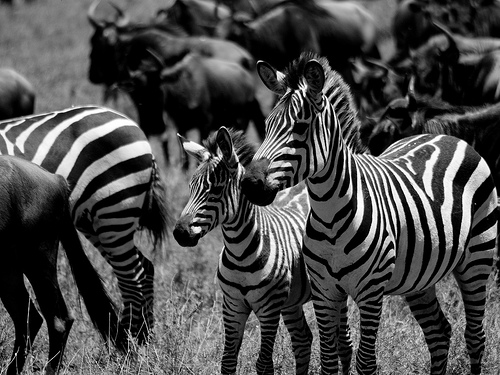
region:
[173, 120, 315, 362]
zebra colt next to mother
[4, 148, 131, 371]
rear legs and tail of horse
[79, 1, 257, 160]
water buffalo or musk ox in background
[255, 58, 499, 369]
zebra next to colt looking to the left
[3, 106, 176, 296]
rear legs and tail of zebra on far left of picture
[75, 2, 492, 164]
herd of water buffalo or musk oxen in background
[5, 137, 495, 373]
grass in field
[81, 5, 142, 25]
horns of large water buffalo in background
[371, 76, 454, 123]
water buffalo looking to the right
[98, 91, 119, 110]
water buffalo in background's beard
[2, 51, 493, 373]
zebras standing on the grass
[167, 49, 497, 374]
baby zebra standing next to an adult zebra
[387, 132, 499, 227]
black and white stripes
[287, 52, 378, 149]
tall hair along the neck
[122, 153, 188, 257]
hair on the tail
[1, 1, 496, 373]
a bunch of animals on the grass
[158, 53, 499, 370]
two black and white zebras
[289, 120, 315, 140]
black eye on the side of the head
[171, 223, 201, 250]
tip of the snout is black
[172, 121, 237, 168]
two long ears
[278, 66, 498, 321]
white and black zebra on grass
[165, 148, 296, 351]
white and black zebra on grass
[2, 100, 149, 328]
white and black zebra on grass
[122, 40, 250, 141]
brown wildebeest in grass field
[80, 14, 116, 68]
brown wildebeest in grass field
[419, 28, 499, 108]
brown wildebeest in grass field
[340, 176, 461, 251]
black and white stripes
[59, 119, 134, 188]
black and white stripes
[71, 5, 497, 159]
Herd of wildebeest in field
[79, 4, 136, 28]
Horns on wildebeest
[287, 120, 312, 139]
Black eye of zebra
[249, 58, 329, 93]
Alert ears on zebra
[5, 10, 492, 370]
Dried grass on plain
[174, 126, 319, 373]
Young zebra in field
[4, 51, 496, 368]
Zebra's in dry grass plain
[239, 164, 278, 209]
Black nose on zebra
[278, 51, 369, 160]
Mane hair on zebra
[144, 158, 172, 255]
Tail hairs of zebra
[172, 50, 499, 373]
Zebras on the grass.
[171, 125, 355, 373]
A baby zebra in the grass.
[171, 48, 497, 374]
Momma and baby zebras.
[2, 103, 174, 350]
Part of a zebra.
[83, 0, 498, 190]
Oxen in a field.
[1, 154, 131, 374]
Part of a cow.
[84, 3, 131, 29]
Horns on a bull.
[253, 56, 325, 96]
Two zebra ears.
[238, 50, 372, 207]
A zebras head and mane.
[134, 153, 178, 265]
A zebras bushy tail.